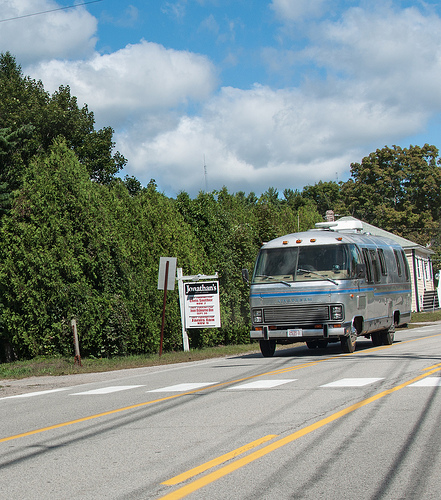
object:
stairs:
[419, 290, 440, 312]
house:
[308, 210, 437, 313]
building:
[310, 210, 435, 313]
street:
[0, 320, 440, 499]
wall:
[347, 105, 396, 150]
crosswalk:
[0, 375, 440, 396]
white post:
[176, 268, 221, 353]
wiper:
[298, 268, 339, 285]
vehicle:
[242, 231, 412, 357]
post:
[159, 261, 169, 357]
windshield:
[252, 244, 351, 284]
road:
[0, 320, 441, 499]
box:
[317, 377, 385, 387]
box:
[227, 379, 298, 390]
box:
[145, 382, 219, 393]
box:
[69, 385, 145, 396]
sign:
[183, 281, 221, 329]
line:
[156, 364, 441, 500]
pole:
[71, 319, 82, 366]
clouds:
[0, 0, 441, 200]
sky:
[2, 0, 439, 200]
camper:
[244, 226, 410, 354]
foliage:
[4, 173, 116, 309]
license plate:
[286, 329, 302, 338]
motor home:
[216, 214, 432, 360]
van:
[230, 204, 417, 365]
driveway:
[0, 322, 440, 500]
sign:
[157, 257, 177, 291]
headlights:
[331, 306, 343, 320]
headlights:
[253, 310, 262, 323]